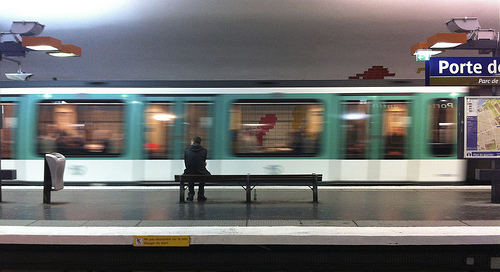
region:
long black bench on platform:
[173, 175, 323, 209]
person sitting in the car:
[31, 114, 94, 158]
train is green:
[11, 91, 431, 138]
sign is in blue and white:
[421, 52, 499, 85]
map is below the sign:
[464, 93, 499, 165]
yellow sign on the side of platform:
[121, 232, 197, 252]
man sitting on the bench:
[168, 129, 250, 216]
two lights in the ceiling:
[16, 34, 102, 61]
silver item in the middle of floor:
[36, 159, 96, 191]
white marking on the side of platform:
[0, 224, 499, 232]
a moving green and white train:
[0, 81, 468, 181]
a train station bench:
[173, 172, 323, 203]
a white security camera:
[4, 72, 31, 82]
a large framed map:
[464, 94, 499, 158]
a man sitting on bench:
[184, 136, 208, 202]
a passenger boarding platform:
[0, 185, 498, 244]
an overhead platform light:
[21, 35, 58, 51]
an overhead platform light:
[47, 43, 81, 58]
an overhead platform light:
[426, 31, 466, 51]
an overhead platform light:
[408, 41, 442, 58]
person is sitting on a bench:
[160, 127, 238, 201]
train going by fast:
[7, 98, 447, 156]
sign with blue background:
[422, 57, 489, 77]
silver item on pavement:
[43, 153, 74, 201]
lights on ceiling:
[13, 17, 105, 71]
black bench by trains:
[170, 178, 322, 193]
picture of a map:
[461, 101, 498, 159]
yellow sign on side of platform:
[125, 227, 208, 257]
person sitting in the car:
[48, 122, 82, 149]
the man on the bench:
[172, 129, 216, 203]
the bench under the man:
[173, 168, 324, 208]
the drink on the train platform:
[250, 183, 259, 202]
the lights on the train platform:
[0, 5, 88, 59]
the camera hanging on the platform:
[0, 56, 36, 88]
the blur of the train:
[216, 83, 456, 182]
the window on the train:
[222, 102, 331, 159]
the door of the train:
[334, 96, 414, 183]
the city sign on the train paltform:
[452, 94, 499, 159]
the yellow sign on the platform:
[127, 230, 195, 250]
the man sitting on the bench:
[182, 135, 210, 201]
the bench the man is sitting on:
[173, 173, 321, 203]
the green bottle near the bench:
[252, 187, 257, 199]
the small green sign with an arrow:
[415, 52, 430, 60]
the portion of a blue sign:
[425, 57, 499, 86]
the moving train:
[0, 79, 469, 186]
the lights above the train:
[20, 32, 466, 57]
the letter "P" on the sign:
[437, 59, 448, 72]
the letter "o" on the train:
[449, 62, 458, 73]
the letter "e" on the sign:
[472, 62, 481, 73]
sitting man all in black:
[182, 135, 209, 200]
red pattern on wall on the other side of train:
[253, 113, 278, 146]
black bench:
[172, 173, 323, 203]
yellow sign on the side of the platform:
[131, 234, 191, 246]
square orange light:
[22, 37, 63, 51]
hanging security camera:
[0, 51, 34, 82]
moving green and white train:
[0, 79, 475, 183]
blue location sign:
[425, 55, 497, 85]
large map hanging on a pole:
[463, 95, 498, 157]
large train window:
[228, 97, 327, 156]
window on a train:
[3, 99, 19, 184]